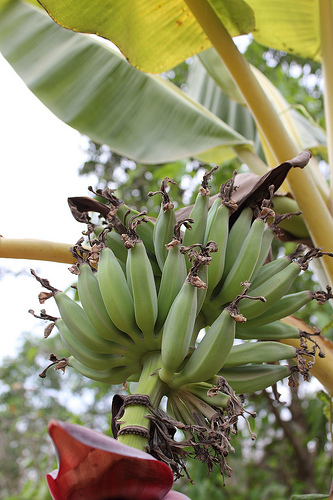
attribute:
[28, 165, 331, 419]
bananas — green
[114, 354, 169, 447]
stem — green, thin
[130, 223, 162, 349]
banana — green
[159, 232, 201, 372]
banana — green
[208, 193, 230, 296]
banana — green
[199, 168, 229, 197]
objects — dark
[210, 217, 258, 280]
bananas — top bunch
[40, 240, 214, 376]
bananas — middle bunch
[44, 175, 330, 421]
fruit — green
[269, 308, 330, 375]
vine — yellow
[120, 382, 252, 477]
branches — dried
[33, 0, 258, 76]
leaf — plantain, big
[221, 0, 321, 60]
leaf — plantain, big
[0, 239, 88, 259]
stem — yellow, horizontal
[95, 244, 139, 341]
banana — green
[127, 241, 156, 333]
banana — green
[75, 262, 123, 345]
banana — green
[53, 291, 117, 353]
banana — green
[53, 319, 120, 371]
banana — green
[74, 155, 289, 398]
plant — green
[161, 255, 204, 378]
banana — green, unripe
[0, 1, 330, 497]
tree — banana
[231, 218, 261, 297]
banana — green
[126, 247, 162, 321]
banana — green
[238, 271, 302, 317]
banana — green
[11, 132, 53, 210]
sky — white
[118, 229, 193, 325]
banana — unripe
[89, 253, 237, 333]
banana — unripe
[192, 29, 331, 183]
branches — yellow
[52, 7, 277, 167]
leaves — big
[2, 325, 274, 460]
trees — in the back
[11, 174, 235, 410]
banana — unripe 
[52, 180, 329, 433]
banana — unripe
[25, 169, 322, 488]
plant — small, green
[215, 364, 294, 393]
banana — green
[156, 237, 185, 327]
banana — green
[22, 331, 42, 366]
leaves — Blurred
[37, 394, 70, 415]
leaves — Blurred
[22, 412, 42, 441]
leaves — Blurred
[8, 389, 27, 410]
leaves — Blurred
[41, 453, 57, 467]
leaves — Blurred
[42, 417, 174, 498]
leaf — red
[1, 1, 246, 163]
leaf — Large, yellow , green, big, plantain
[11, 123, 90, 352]
sky — white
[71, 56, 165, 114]
leaves — green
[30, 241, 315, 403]
cluster — first